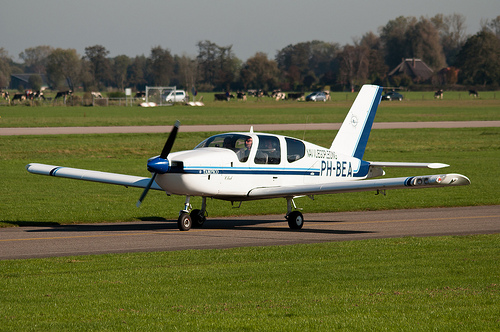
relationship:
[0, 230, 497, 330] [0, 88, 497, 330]
grass in field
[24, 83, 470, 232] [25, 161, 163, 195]
airplane has wing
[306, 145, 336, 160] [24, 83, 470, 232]
writing on airplane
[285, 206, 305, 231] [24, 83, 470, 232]
wheel on back of airplane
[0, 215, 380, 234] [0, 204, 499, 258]
shadow on runway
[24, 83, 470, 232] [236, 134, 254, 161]
airplane has man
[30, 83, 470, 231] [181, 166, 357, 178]
airplane has stripes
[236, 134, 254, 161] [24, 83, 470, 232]
man inside airplane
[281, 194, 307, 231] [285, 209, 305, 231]
landing gear with wheel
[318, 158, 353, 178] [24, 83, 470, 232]
letters on side of airplane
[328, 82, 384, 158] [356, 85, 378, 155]
tail with stripe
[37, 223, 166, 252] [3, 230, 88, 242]
asphalt with stripe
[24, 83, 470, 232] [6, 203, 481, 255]
airplane on a runway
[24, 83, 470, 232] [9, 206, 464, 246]
airplane on a runway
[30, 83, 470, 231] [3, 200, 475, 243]
airplane on a runway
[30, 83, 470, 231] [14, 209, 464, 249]
airplane on a runway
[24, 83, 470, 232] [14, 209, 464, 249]
airplane on a runway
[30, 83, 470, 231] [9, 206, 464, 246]
airplane on a runway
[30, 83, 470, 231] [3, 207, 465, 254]
airplane on a runway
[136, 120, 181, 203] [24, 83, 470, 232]
propeller on front of airplane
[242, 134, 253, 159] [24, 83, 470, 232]
man inside a airplane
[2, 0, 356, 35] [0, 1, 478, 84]
blue of sky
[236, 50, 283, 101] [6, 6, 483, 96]
trees on horizon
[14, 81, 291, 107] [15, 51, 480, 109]
animals in distance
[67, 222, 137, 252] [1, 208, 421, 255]
surface of runway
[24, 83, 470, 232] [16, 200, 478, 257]
airplane on top of runway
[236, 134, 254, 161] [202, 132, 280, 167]
man in cockpit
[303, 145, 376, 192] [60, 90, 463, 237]
letters on plane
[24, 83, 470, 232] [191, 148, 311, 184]
airplane with stripes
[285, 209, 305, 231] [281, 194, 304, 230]
wheel of landing gear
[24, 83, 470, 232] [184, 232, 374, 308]
airplane on ground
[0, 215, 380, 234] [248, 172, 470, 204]
shadow of wing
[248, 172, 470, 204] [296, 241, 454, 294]
wing on ground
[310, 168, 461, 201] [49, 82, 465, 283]
wing of airplane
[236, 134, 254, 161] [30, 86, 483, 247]
man inside plane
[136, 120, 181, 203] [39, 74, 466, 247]
propeller of plane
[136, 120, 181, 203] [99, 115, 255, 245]
propeller on front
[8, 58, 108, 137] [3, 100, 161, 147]
cows on field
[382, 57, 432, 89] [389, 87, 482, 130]
building behind field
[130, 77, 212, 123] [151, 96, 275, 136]
car across field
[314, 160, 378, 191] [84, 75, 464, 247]
letters on plane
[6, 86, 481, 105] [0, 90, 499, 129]
cows eating grass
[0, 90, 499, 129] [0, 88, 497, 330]
grass in field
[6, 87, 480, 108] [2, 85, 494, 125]
cows grazing in farm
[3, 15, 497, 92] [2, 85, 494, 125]
trees surrounding farm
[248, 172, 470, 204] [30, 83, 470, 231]
wing belongs to airplane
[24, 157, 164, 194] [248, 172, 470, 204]
wing belongs to wing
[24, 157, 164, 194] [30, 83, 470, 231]
wing belongs to airplane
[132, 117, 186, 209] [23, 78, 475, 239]
propeller belongs to airplane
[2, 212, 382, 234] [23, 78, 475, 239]
shadow cast by airplane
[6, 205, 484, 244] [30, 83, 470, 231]
runway underneath white airplane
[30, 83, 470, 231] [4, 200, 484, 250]
airplane above runway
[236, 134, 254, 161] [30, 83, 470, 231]
man inside white airplane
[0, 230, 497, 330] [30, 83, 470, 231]
grass in front of airplane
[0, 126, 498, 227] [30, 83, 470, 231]
grass behind white airplane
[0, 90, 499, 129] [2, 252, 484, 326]
grass behind white grass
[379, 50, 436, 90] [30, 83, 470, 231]
building behind airplane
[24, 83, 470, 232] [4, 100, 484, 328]
airplane on ground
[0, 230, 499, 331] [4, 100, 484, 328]
grass on ground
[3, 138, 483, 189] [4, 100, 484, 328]
grass on ground